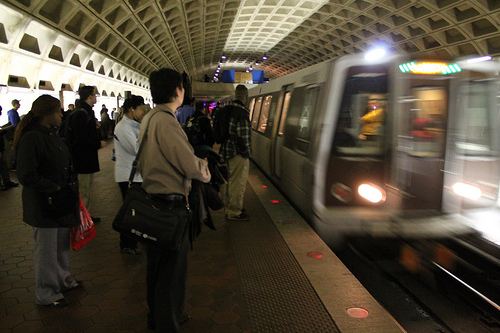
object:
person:
[126, 67, 211, 330]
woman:
[11, 95, 82, 307]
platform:
[3, 167, 342, 326]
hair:
[147, 62, 181, 100]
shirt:
[132, 103, 217, 201]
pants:
[31, 225, 76, 305]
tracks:
[380, 234, 499, 329]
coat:
[136, 108, 210, 192]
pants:
[140, 192, 195, 330]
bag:
[116, 115, 188, 249]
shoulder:
[153, 104, 177, 132]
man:
[127, 63, 214, 331]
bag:
[189, 145, 216, 187]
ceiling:
[16, 1, 498, 75]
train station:
[7, 2, 498, 328]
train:
[245, 47, 490, 246]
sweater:
[132, 104, 214, 195]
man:
[218, 83, 254, 220]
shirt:
[211, 100, 255, 165]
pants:
[212, 150, 251, 219]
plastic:
[72, 197, 117, 270]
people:
[65, 85, 102, 223]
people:
[184, 102, 213, 162]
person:
[9, 92, 90, 312]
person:
[109, 93, 146, 261]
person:
[217, 77, 259, 225]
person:
[97, 110, 113, 154]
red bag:
[74, 192, 98, 252]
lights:
[313, 50, 497, 254]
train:
[353, 178, 396, 203]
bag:
[67, 194, 100, 249]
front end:
[322, 51, 499, 238]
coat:
[17, 124, 88, 220]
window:
[410, 86, 445, 160]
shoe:
[37, 297, 71, 309]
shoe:
[67, 281, 81, 291]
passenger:
[358, 95, 383, 140]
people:
[12, 61, 297, 321]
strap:
[131, 137, 145, 167]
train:
[272, 79, 488, 189]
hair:
[8, 92, 56, 137]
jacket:
[24, 130, 76, 240]